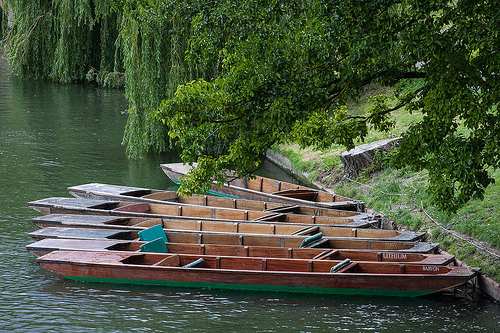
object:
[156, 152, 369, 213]
boats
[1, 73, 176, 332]
water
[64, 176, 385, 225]
boats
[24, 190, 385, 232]
boats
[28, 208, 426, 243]
boats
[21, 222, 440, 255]
boats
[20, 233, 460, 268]
boats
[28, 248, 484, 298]
boats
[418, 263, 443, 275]
letters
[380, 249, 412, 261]
letters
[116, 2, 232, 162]
tree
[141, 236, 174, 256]
seats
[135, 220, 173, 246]
seats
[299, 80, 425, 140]
limbs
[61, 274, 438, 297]
stripe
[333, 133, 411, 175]
stump